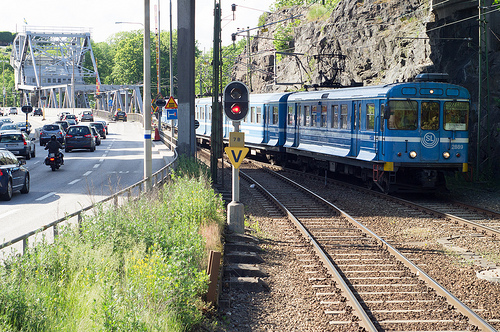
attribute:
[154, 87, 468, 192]
train — blue, white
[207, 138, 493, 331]
gravel — small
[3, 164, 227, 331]
weeds — overgrown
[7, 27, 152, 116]
bridge — steel, metal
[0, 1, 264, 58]
sky — clear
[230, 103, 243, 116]
light — red, on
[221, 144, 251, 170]
sign — yellow, triangular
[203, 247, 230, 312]
post — wooden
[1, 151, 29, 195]
car — blue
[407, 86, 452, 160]
lights — on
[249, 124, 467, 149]
stripe — white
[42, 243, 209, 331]
flowers — yellow